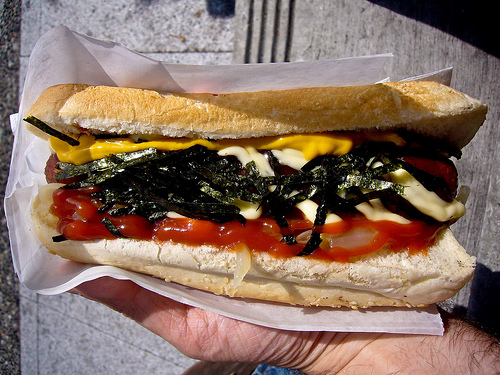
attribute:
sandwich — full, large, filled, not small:
[25, 86, 487, 256]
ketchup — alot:
[55, 192, 426, 260]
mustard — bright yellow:
[52, 130, 353, 165]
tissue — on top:
[22, 26, 407, 91]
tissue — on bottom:
[6, 203, 447, 336]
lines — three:
[245, 0, 295, 66]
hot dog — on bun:
[358, 144, 459, 218]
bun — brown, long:
[28, 81, 489, 153]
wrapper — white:
[4, 27, 452, 338]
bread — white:
[81, 232, 472, 299]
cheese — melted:
[219, 145, 339, 221]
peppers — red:
[105, 216, 145, 239]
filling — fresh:
[45, 131, 467, 261]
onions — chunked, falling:
[228, 242, 253, 295]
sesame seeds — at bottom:
[312, 299, 423, 310]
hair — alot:
[427, 306, 499, 375]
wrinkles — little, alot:
[208, 320, 279, 362]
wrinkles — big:
[275, 327, 355, 374]